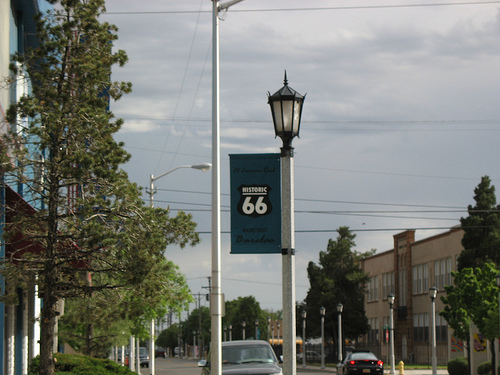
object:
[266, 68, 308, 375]
lamppost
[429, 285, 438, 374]
lamppost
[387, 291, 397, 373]
lamppost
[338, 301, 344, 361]
lamppost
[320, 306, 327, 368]
lamppost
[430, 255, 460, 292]
windows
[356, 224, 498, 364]
building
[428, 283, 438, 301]
streetlamp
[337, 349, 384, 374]
car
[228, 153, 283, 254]
sign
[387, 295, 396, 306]
streetlight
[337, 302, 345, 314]
streetlight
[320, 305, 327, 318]
streetlight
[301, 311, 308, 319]
streetlight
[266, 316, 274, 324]
streetlight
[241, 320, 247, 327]
streetlight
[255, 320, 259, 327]
streetlight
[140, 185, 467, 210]
wire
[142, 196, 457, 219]
wire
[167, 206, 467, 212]
wire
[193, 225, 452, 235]
wire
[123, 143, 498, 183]
wire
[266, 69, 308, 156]
lamps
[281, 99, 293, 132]
glass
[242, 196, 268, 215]
numbers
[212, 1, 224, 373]
pole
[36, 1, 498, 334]
cloud cover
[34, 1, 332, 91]
sky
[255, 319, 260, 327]
light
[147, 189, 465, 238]
wires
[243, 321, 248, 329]
street light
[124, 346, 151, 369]
car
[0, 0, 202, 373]
tree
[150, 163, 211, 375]
street light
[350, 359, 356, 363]
lights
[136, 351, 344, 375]
street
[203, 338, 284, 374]
car